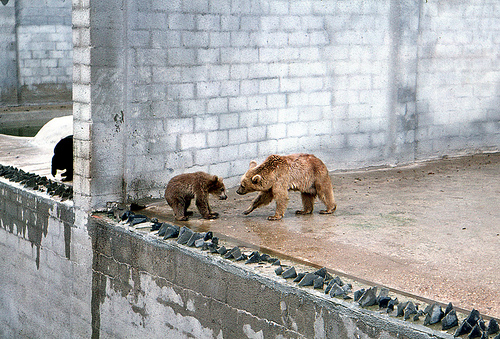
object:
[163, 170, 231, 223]
small bear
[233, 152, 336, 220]
big bear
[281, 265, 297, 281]
stone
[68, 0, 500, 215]
wall